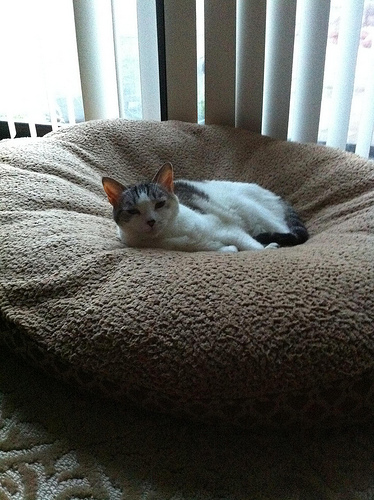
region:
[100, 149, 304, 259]
black and white cat laying in bed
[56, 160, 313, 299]
black and white cat laying on cusion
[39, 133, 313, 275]
black and white cat laying down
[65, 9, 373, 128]
blinds are closed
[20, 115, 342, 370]
large fuzzy bed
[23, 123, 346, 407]
cat laying in large seat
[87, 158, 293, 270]
cat with pointy ears staring forward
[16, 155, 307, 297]
black and white cat looking straight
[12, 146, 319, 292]
black and white cat curled up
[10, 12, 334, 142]
sunlight shining through blinds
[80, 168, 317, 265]
a grey and white tabby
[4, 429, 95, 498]
a fleur de lis design in the beige carpet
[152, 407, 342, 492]
a dark shadow on the carpet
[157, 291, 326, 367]
a brown pet pillow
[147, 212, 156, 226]
a cat's black nose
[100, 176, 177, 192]
the pink inner ears of a cat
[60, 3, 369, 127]
white vertical blinds on a window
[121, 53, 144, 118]
sunlight coming through the window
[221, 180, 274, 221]
the white back end of the cat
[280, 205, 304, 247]
a gray and black striped cat tail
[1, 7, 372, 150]
window with white vertical blinds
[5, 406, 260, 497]
brown and tan carpeting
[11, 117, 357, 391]
comfortable looking cat bed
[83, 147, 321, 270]
cat resting in a bed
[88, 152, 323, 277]
black and white cat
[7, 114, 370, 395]
brown cat bed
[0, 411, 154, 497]
carpet with a raised pattern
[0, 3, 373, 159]
the blinds are open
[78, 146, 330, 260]
the cat's eyes are open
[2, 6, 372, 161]
daylight comes in through the window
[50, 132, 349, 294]
gray, black, and white cat laying on bed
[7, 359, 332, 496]
damask rug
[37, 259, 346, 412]
brown fleece cat bed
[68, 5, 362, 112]
vertical slat blinds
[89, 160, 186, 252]
white and gray cat face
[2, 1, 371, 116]
window with blinds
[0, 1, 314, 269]
feline resting in the sun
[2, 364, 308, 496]
tan and cream colored rug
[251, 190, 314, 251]
black and gray striped cat's tail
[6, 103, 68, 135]
black window sill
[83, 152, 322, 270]
a cat lying on a couch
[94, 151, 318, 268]
cat is white and gray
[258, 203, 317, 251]
the tail of cat is gray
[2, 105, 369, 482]
couch is indented by the weight of cat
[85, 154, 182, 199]
ears on the head are pointy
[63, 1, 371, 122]
blinds behind a couch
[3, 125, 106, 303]
couch is wrinkled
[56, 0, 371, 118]
blinds are long and whide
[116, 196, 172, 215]
eyes of cat are open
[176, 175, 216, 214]
black spot on body of cat